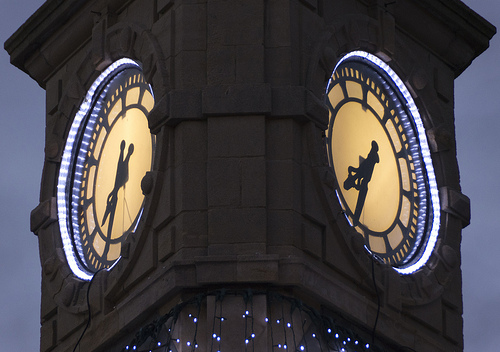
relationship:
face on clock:
[336, 100, 405, 229] [306, 44, 454, 283]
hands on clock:
[339, 139, 386, 228] [306, 44, 454, 283]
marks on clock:
[333, 75, 387, 109] [306, 44, 454, 283]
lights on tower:
[123, 307, 376, 351] [0, 0, 495, 350]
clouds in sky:
[6, 93, 38, 183] [461, 115, 499, 259]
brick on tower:
[168, 22, 303, 186] [0, 0, 495, 350]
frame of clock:
[295, 25, 466, 325] [306, 44, 454, 283]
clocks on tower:
[53, 49, 445, 283] [0, 0, 495, 350]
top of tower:
[1, 2, 496, 38] [0, 0, 495, 350]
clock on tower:
[306, 44, 454, 283] [0, 0, 495, 350]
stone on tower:
[174, 181, 287, 253] [0, 0, 495, 350]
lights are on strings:
[123, 307, 376, 351] [218, 285, 320, 317]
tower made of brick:
[0, 0, 495, 350] [168, 22, 303, 186]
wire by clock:
[363, 251, 385, 345] [306, 44, 454, 283]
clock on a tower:
[306, 44, 454, 283] [0, 0, 495, 350]